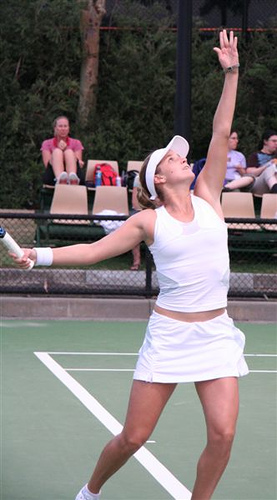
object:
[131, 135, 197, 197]
visor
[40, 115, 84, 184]
female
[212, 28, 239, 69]
hand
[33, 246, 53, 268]
wrist band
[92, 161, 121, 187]
backpack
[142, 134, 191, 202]
visor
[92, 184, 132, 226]
seat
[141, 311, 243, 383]
skirt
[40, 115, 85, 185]
memeber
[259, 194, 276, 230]
seat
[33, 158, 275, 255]
stands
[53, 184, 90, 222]
seat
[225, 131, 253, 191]
woman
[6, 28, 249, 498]
tennis player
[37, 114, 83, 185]
woman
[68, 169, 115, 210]
chair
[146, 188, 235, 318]
tennis top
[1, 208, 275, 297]
fence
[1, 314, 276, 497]
court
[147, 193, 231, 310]
tank top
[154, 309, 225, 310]
above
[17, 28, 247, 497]
player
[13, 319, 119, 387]
court surface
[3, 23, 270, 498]
tennis match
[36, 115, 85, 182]
audience member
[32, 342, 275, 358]
line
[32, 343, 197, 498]
line